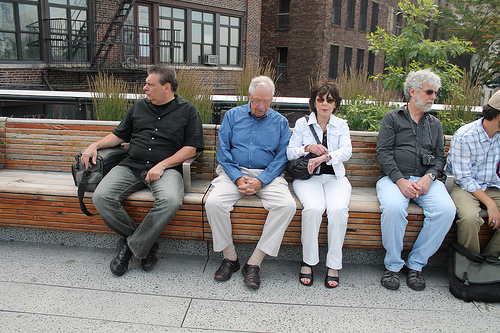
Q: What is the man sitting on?
A: A bench.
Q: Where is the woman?
A: On a bench.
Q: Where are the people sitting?
A: On a bench.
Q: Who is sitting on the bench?
A: Five people.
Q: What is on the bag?
A: The man's arm.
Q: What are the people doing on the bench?
A: Sitting.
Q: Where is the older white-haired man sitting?
A: On the bench.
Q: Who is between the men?
A: A woman.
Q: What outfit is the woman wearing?
A: White.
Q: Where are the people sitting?
A: On a bench.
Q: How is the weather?
A: Bright and shiny.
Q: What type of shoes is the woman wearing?
A: Open.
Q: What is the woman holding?
A: A purse.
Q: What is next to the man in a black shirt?
A: A bag.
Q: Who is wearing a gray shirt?
A: The man.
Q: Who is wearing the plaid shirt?
A: Guy on the right.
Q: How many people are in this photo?
A: 5.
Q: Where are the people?
A: On the bench.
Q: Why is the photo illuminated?
A: It is daytime.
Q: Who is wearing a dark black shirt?
A: The man on the left.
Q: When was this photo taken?
A: During the day.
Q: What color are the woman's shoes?
A: Black.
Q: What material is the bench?
A: Wooden.